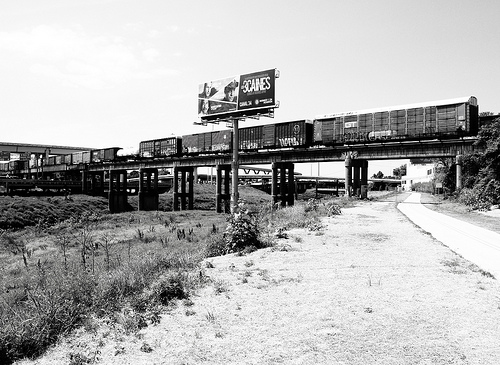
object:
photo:
[0, 0, 499, 365]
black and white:
[200, 76, 239, 114]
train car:
[313, 95, 480, 145]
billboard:
[196, 67, 279, 120]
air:
[60, 47, 113, 64]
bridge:
[102, 144, 452, 172]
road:
[396, 191, 499, 279]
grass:
[148, 225, 268, 244]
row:
[138, 96, 479, 159]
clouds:
[466, 28, 491, 73]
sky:
[95, 38, 169, 72]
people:
[222, 82, 238, 102]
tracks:
[114, 139, 472, 163]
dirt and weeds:
[186, 267, 221, 295]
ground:
[0, 191, 500, 364]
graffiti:
[279, 137, 299, 147]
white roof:
[312, 95, 476, 120]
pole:
[230, 120, 237, 217]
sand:
[219, 256, 237, 277]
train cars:
[236, 119, 313, 150]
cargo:
[182, 129, 233, 153]